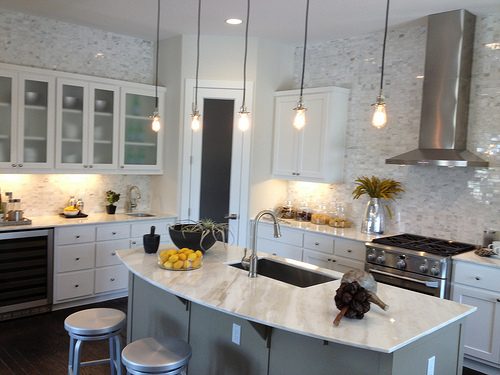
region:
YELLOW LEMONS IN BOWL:
[152, 243, 210, 284]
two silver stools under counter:
[58, 302, 194, 373]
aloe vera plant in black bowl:
[162, 200, 227, 257]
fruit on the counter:
[329, 267, 403, 332]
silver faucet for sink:
[234, 207, 294, 281]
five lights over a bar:
[125, 96, 398, 163]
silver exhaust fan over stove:
[360, 105, 480, 259]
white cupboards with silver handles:
[52, 218, 142, 300]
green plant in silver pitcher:
[300, 168, 403, 273]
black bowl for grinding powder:
[131, 217, 167, 259]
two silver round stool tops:
[60, 304, 190, 372]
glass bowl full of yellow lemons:
[156, 245, 204, 272]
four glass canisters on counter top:
[273, 193, 355, 228]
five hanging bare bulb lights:
[141, 94, 389, 137]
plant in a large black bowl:
[168, 213, 240, 251]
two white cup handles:
[488, 238, 498, 268]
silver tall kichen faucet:
[239, 205, 287, 278]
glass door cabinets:
[0, 71, 168, 178]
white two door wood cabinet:
[269, 81, 347, 184]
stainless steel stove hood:
[384, 41, 491, 177]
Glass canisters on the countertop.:
[275, 195, 350, 230]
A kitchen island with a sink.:
[100, 230, 480, 370]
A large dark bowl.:
[167, 220, 214, 250]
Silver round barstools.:
[62, 301, 195, 371]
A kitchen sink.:
[228, 207, 342, 293]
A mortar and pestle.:
[142, 226, 161, 253]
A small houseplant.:
[105, 188, 120, 214]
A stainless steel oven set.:
[367, 231, 479, 322]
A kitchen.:
[3, 2, 498, 372]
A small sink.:
[126, 182, 159, 224]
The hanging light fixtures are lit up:
[146, 0, 396, 132]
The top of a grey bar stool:
[63, 306, 123, 373]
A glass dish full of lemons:
[156, 245, 203, 271]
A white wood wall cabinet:
[271, 85, 347, 184]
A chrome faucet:
[246, 206, 283, 280]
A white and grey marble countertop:
[113, 227, 480, 364]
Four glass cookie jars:
[278, 196, 353, 230]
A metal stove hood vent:
[384, 66, 491, 168]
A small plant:
[103, 187, 122, 215]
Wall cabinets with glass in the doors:
[0, 60, 164, 176]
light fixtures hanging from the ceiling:
[149, 0, 391, 132]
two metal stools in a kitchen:
[63, 305, 192, 372]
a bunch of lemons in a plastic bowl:
[158, 248, 202, 269]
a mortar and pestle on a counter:
[142, 225, 160, 253]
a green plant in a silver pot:
[352, 175, 404, 233]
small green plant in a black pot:
[103, 190, 120, 216]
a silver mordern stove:
[365, 230, 472, 294]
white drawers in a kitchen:
[56, 219, 181, 304]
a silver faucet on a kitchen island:
[249, 208, 280, 276]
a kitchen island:
[114, 232, 476, 373]